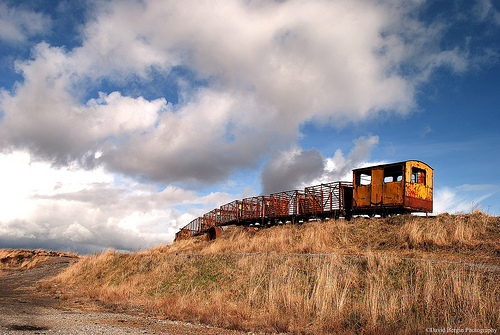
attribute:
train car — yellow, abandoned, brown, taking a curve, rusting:
[337, 157, 438, 218]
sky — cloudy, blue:
[3, 4, 499, 233]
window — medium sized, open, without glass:
[381, 165, 404, 183]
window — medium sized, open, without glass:
[352, 169, 374, 186]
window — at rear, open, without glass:
[411, 166, 429, 189]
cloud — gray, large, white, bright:
[15, 10, 439, 171]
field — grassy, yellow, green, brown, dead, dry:
[71, 216, 496, 334]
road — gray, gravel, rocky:
[1, 255, 224, 333]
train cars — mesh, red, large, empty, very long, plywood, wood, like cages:
[177, 179, 351, 240]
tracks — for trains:
[412, 212, 498, 220]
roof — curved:
[353, 157, 440, 176]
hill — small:
[94, 223, 493, 315]